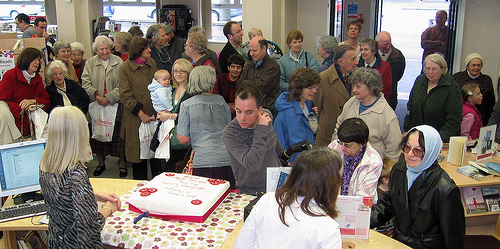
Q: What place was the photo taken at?
A: It was taken at the store.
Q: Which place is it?
A: It is a store.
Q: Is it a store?
A: Yes, it is a store.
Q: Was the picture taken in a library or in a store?
A: It was taken at a store.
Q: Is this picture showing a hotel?
A: No, the picture is showing a store.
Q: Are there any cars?
A: No, there are no cars.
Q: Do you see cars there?
A: No, there are no cars.